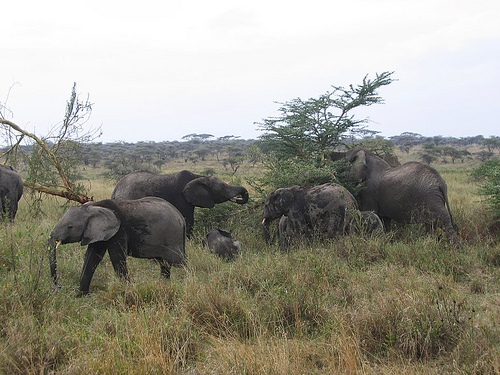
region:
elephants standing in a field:
[29, 41, 497, 343]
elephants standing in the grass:
[19, 95, 498, 352]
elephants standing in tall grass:
[49, 120, 486, 332]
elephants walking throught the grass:
[37, 76, 494, 328]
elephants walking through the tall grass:
[23, 98, 498, 374]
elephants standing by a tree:
[44, 58, 499, 365]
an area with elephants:
[37, 62, 492, 348]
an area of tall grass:
[2, 76, 498, 338]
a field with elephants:
[4, 58, 480, 368]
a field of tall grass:
[14, 92, 493, 293]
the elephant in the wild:
[20, 175, 180, 280]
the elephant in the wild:
[108, 156, 262, 230]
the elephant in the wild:
[36, 203, 231, 292]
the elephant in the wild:
[263, 175, 346, 280]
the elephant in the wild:
[357, 180, 482, 270]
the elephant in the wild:
[269, 130, 369, 242]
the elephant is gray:
[40, 188, 192, 284]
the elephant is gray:
[92, 145, 287, 242]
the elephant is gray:
[232, 196, 434, 284]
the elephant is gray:
[285, 134, 457, 259]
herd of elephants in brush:
[43, 146, 465, 313]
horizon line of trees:
[98, 127, 255, 154]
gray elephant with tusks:
[40, 195, 193, 306]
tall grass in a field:
[262, 246, 499, 374]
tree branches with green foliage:
[268, 62, 395, 143]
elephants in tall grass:
[42, 139, 468, 296]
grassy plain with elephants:
[41, 146, 462, 362]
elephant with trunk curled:
[120, 166, 257, 233]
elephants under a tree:
[250, 60, 460, 260]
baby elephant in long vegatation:
[197, 221, 246, 269]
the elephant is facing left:
[45, 195, 192, 302]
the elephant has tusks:
[47, 238, 61, 250]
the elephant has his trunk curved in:
[223, 180, 250, 206]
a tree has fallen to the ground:
[0, 115, 110, 208]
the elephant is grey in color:
[46, 195, 191, 304]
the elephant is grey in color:
[111, 170, 247, 246]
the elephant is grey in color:
[349, 150, 449, 237]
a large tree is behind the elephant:
[265, 64, 397, 176]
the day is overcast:
[6, 0, 491, 147]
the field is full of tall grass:
[0, 145, 497, 367]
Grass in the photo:
[195, 290, 414, 364]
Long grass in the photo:
[230, 260, 395, 342]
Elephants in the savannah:
[52, 141, 447, 267]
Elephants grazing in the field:
[56, 140, 456, 241]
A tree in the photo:
[279, 59, 358, 175]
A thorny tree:
[250, 61, 365, 196]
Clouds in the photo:
[206, 30, 309, 98]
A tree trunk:
[44, 151, 87, 201]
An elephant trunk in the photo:
[47, 229, 69, 258]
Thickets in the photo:
[120, 127, 248, 172]